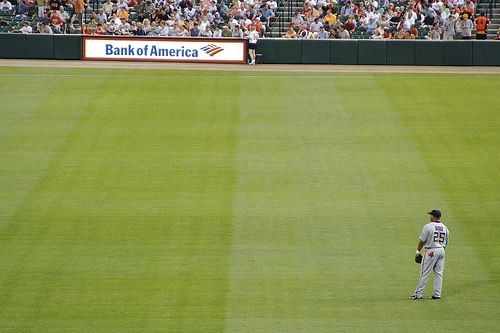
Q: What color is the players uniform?
A: Gray.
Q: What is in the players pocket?
A: A red rag.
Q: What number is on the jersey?
A: 25.